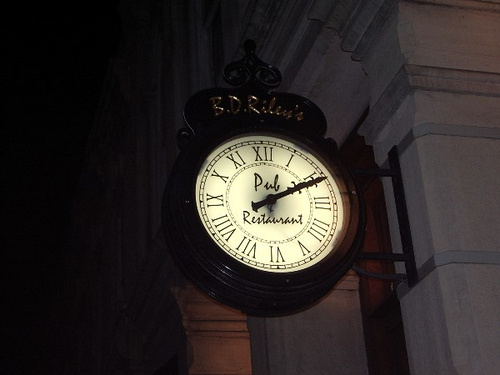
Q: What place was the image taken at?
A: It was taken at the pub.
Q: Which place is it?
A: It is a pub.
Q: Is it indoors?
A: Yes, it is indoors.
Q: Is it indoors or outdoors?
A: It is indoors.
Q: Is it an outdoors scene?
A: No, it is indoors.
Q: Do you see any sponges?
A: No, there are no sponges.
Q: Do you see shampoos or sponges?
A: No, there are no sponges or shampoos.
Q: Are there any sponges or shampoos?
A: No, there are no sponges or shampoos.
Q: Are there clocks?
A: Yes, there is a clock.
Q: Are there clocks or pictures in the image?
A: Yes, there is a clock.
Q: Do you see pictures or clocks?
A: Yes, there is a clock.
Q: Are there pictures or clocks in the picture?
A: Yes, there is a clock.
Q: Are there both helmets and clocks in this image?
A: No, there is a clock but no helmets.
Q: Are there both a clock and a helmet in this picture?
A: No, there is a clock but no helmets.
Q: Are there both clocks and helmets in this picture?
A: No, there is a clock but no helmets.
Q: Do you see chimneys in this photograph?
A: No, there are no chimneys.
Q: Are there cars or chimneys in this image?
A: No, there are no chimneys or cars.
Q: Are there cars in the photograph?
A: No, there are no cars.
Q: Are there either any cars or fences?
A: No, there are no cars or fences.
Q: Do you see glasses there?
A: No, there are no glasses.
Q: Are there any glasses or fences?
A: No, there are no glasses or fences.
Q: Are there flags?
A: No, there are no flags.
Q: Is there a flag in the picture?
A: No, there are no flags.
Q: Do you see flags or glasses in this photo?
A: No, there are no flags or glasses.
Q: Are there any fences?
A: No, there are no fences.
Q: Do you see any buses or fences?
A: No, there are no fences or buses.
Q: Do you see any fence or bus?
A: No, there are no fences or buses.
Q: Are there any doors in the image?
A: Yes, there is a door.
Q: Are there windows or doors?
A: Yes, there is a door.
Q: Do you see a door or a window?
A: Yes, there is a door.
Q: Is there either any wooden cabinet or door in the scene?
A: Yes, there is a wood door.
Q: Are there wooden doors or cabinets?
A: Yes, there is a wood door.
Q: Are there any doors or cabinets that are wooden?
A: Yes, the door is wooden.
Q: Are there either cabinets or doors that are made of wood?
A: Yes, the door is made of wood.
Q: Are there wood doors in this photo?
A: Yes, there is a wood door.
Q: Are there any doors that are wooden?
A: Yes, there is a door that is wooden.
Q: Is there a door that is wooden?
A: Yes, there is a door that is wooden.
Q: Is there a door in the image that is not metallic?
A: Yes, there is a wooden door.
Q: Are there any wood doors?
A: Yes, there is a door that is made of wood.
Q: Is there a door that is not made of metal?
A: Yes, there is a door that is made of wood.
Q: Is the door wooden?
A: Yes, the door is wooden.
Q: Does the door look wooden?
A: Yes, the door is wooden.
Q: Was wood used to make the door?
A: Yes, the door is made of wood.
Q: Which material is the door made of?
A: The door is made of wood.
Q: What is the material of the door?
A: The door is made of wood.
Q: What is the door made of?
A: The door is made of wood.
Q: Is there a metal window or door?
A: No, there is a door but it is wooden.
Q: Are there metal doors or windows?
A: No, there is a door but it is wooden.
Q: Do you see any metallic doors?
A: No, there is a door but it is wooden.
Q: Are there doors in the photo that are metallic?
A: No, there is a door but it is wooden.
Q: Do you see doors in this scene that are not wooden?
A: No, there is a door but it is wooden.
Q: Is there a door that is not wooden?
A: No, there is a door but it is wooden.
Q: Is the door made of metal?
A: No, the door is made of wood.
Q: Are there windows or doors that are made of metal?
A: No, there is a door but it is made of wood.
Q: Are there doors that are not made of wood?
A: No, there is a door but it is made of wood.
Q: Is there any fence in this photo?
A: No, there are no fences.